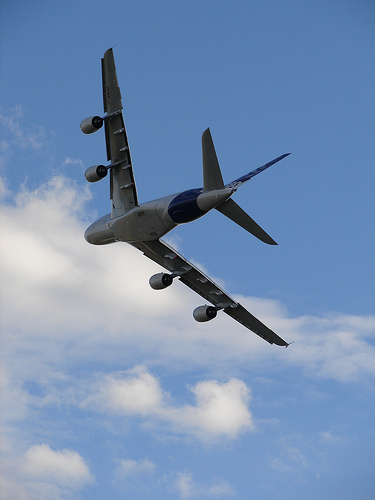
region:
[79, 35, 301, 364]
airplane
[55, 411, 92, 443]
white clouds in blue sky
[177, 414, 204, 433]
white clouds in blue sky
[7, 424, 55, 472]
white clouds in blue sky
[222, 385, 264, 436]
white clouds in blue sky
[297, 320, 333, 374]
white clouds in blue sky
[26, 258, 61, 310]
white clouds in blue sky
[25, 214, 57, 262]
white clouds in blue sky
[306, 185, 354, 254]
white clouds in blue sky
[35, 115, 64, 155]
white clouds in blue sky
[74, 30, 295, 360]
airplane in air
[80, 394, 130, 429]
white clouds in blue sky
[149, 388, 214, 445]
white clouds in blue sky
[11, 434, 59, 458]
white clouds in blue sky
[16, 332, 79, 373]
white clouds in blue sky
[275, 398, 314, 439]
white clouds in blue sky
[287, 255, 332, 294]
white clouds in blue sky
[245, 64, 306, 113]
white clouds in blue sky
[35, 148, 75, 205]
white clouds in blue sky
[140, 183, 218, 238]
plane has a blue stripe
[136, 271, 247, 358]
two engines on the wing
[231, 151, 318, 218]
tail of plane is blue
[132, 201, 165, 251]
openings for landing gear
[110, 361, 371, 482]
a few clouds in the sky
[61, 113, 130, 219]
two engines on the wing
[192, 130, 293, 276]
two small wings to the side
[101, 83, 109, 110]
some writing on the bottom of the wing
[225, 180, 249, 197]
white writing on the tail of the plane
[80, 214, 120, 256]
nose of the airplane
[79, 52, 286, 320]
the plane is white and blue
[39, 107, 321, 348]
the plane is two colors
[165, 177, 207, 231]
the tail is blue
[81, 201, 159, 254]
the base is white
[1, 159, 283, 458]
Clouds in the sky are white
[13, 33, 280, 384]
the plane is in the air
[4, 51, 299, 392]
the plane is turning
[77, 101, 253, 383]
the plane has four propellers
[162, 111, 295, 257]
the tail has 4 wings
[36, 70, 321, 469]
the sky is partly cloudy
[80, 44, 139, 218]
left wing on a plane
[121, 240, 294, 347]
right wing on a plane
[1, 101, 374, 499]
clouds in a blue sky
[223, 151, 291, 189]
blue tail on a plane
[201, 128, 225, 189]
rear left wing on a plane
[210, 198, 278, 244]
rear right wing on a plane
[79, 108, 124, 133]
propeller on plane wing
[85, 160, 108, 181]
propeller on plane wing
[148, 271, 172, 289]
propeller on plane wing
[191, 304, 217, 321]
propeller on plane wing